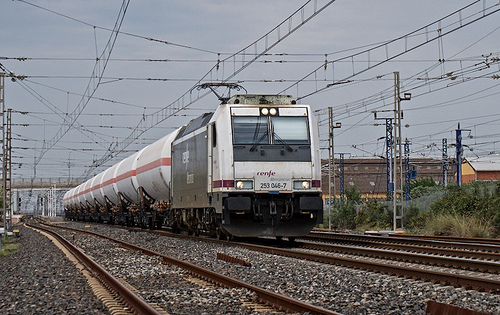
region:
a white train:
[56, 86, 332, 245]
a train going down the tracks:
[57, 92, 337, 254]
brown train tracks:
[15, 196, 344, 313]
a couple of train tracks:
[70, 197, 496, 296]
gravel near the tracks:
[16, 201, 81, 311]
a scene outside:
[0, 5, 485, 310]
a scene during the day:
[5, 15, 490, 285]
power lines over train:
[12, 12, 482, 157]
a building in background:
[295, 148, 493, 216]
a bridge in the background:
[7, 152, 92, 201]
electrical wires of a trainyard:
[37, 16, 492, 91]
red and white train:
[55, 91, 342, 243]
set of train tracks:
[15, 205, 248, 312]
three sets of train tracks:
[57, 238, 499, 305]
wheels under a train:
[66, 203, 328, 241]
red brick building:
[326, 153, 498, 203]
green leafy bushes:
[343, 199, 498, 230]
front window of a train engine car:
[230, 105, 315, 177]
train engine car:
[170, 93, 325, 242]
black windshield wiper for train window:
[249, 126, 271, 154]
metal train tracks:
[4, 196, 268, 305]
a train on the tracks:
[44, 56, 341, 253]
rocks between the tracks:
[243, 262, 373, 287]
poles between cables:
[0, 37, 66, 223]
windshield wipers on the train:
[244, 119, 299, 151]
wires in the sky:
[55, 9, 157, 143]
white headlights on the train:
[225, 166, 316, 193]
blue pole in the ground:
[362, 103, 421, 229]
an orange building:
[435, 146, 498, 198]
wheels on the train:
[95, 198, 224, 238]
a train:
[112, 95, 382, 233]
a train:
[123, 22, 314, 302]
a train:
[188, 101, 287, 273]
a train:
[191, 77, 342, 308]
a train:
[146, 105, 257, 222]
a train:
[111, 80, 211, 255]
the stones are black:
[324, 266, 339, 295]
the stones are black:
[313, 278, 325, 300]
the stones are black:
[322, 256, 332, 301]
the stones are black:
[313, 295, 334, 314]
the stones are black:
[338, 277, 350, 309]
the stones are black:
[343, 280, 359, 314]